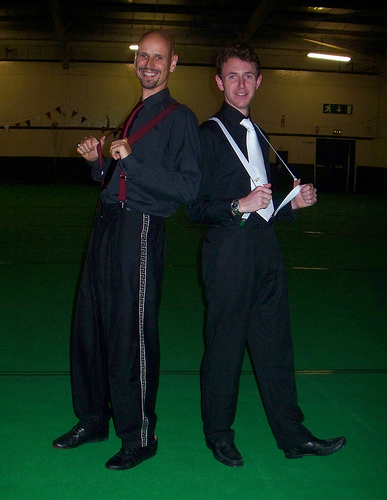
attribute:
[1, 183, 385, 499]
floor — green, large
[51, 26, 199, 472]
man — smiling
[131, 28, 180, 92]
head — bald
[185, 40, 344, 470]
man — smiling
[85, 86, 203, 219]
shirt — black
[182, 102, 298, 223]
shirt — black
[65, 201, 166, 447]
dress pants — black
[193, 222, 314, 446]
dress pants — black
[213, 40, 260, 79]
hair — short, brown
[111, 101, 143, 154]
tie — maroon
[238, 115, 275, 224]
tie — white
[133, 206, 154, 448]
stripe — black, white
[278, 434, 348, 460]
shoe — black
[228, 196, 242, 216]
watch — silver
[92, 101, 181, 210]
suspenders — red, maroon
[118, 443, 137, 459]
laces — black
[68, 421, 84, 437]
laces — black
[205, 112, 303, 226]
suspenders — white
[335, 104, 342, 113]
arrow — down